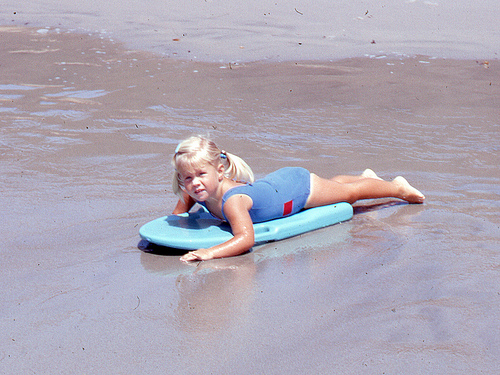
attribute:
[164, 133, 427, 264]
baby's skin — light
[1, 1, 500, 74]
water — calm, coming in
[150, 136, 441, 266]
girl — little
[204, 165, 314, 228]
swimsuit — blue, one piece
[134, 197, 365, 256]
board — blue, light blue, plastic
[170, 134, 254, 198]
girl's hair — long, blonde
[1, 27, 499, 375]
sand — wet, tan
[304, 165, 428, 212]
girl's legs — little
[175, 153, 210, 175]
bangs — blond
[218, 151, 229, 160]
barrette — blue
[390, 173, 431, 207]
foot — bare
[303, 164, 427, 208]
skin — tan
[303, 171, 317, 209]
line — white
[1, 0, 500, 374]
scene — outdoors